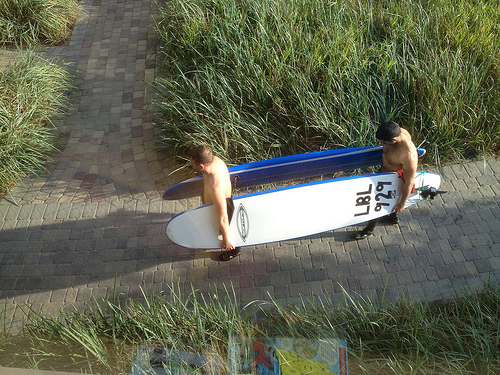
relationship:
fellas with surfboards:
[354, 119, 418, 240] [159, 166, 448, 258]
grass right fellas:
[179, 8, 493, 111] [354, 119, 418, 240]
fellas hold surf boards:
[354, 119, 418, 240] [155, 164, 445, 254]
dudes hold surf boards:
[188, 144, 242, 261] [152, 135, 435, 204]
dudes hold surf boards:
[188, 114, 424, 257] [157, 141, 447, 257]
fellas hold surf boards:
[192, 117, 421, 253] [153, 134, 449, 261]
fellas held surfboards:
[354, 119, 418, 240] [153, 134, 451, 259]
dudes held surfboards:
[188, 114, 424, 257] [193, 117, 423, 255]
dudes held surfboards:
[188, 144, 242, 261] [153, 134, 451, 259]